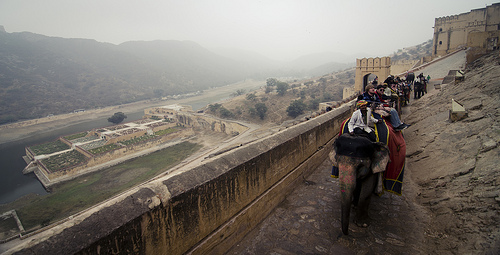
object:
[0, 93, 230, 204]
water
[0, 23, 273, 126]
mountains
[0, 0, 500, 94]
haze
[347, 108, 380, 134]
jacket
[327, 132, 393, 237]
elephant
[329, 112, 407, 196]
cloth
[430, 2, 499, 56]
building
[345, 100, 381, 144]
person